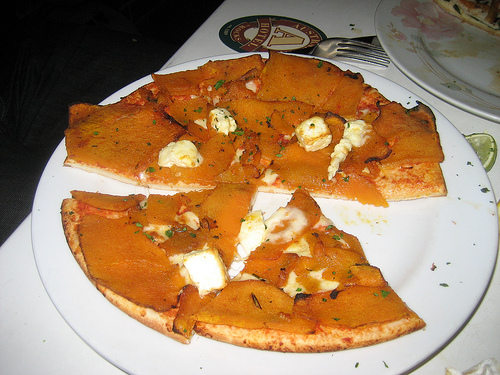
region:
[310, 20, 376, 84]
The fork is silver.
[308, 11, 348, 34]
The table is white.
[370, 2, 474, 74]
The flower is pink.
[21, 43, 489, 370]
The plate is white.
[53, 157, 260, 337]
The pizza has toppings.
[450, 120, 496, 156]
The lime is cut.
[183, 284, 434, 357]
The pizza is cooked.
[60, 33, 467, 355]
The pizza is on the plate.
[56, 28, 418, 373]
The plate is on the table.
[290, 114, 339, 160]
The topping is white.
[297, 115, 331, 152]
Clump of white cheese on pizza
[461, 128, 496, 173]
Line slice on a table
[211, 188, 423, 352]
Slice of pizza on a white plate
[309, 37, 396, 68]
Fork on a white table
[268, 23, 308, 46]
Gold A on a sybol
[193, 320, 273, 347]
Browned crust on a pizza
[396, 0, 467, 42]
Pink flower on a plate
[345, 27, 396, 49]
Knife behind a fork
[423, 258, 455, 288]
Green flakes on a white plate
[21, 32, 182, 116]
Person's blue jeans at a table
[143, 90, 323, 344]
pizza with orange topping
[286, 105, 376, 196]
goat cheese on pizza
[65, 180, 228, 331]
triangular piece of pizza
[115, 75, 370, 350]
pizza cut into triangles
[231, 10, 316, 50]
hotel logo on table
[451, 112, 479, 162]
slice of lime under plate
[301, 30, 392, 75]
silver fork between plates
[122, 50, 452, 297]
pizza on white plate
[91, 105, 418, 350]
pizza with exotic topping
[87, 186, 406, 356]
two slices of pizza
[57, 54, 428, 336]
pizza with orange lox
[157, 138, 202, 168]
lump of melted cheese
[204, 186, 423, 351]
slice of lox pizza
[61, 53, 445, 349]
slices of lox and cheese pizza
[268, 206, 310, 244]
melted cheese on pizza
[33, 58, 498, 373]
white ceramic dinner plate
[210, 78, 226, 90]
parsley speck on pizza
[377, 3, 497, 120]
ceramic dinner plate on table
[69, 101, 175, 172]
slice of orange lox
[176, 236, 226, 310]
piece of white cheese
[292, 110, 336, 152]
cheese on a pizza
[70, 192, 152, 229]
sauce on a cooked pizza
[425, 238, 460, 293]
seasonings on a plate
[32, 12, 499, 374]
a white plate of pizza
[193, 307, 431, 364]
cooked pizza crust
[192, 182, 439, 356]
a slice of pizza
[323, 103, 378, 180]
melted white cheese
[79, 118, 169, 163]
green seasonings on a piece of pizza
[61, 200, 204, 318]
an orange vegetable